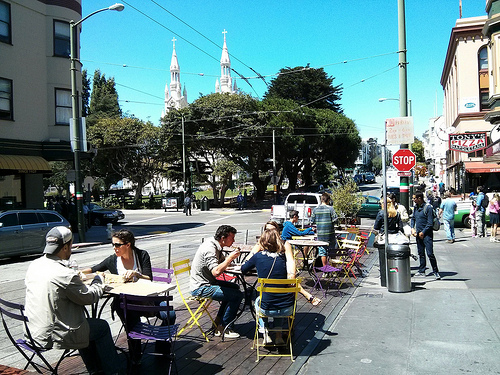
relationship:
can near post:
[386, 239, 414, 295] [382, 124, 390, 289]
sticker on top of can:
[389, 266, 398, 274] [386, 239, 414, 295]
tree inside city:
[164, 92, 257, 211] [2, 4, 495, 372]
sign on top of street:
[392, 151, 416, 170] [346, 219, 498, 362]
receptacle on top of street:
[386, 239, 414, 295] [346, 219, 498, 362]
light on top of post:
[104, 2, 137, 12] [69, 26, 82, 248]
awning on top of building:
[464, 161, 499, 177] [442, 19, 498, 196]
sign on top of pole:
[392, 151, 416, 170] [394, 2, 415, 236]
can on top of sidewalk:
[386, 239, 414, 295] [346, 219, 498, 362]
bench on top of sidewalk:
[128, 197, 170, 211] [121, 202, 242, 212]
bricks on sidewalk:
[254, 356, 295, 375] [192, 314, 499, 375]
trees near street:
[164, 92, 257, 211] [128, 204, 276, 227]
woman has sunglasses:
[89, 229, 158, 278] [110, 242, 127, 250]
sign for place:
[444, 134, 492, 152] [442, 19, 498, 196]